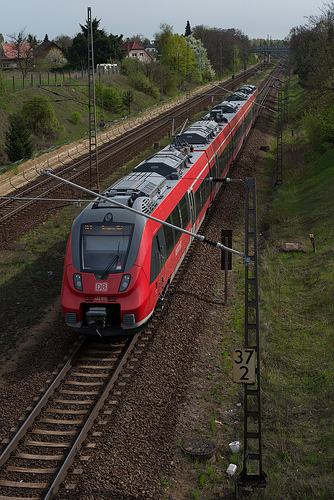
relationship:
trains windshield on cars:
[78, 220, 135, 274] [60, 83, 261, 342]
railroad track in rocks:
[1, 335, 147, 496] [5, 101, 267, 494]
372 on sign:
[234, 349, 255, 380] [228, 344, 258, 384]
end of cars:
[59, 208, 158, 333] [60, 83, 261, 342]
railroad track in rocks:
[1, 335, 147, 499] [2, 193, 245, 497]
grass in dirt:
[194, 305, 238, 492] [160, 291, 246, 493]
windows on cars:
[148, 102, 256, 269] [60, 83, 261, 342]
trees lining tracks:
[280, 4, 333, 149] [0, 330, 136, 493]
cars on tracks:
[60, 83, 261, 342] [2, 337, 145, 497]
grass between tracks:
[258, 79, 333, 498] [2, 337, 145, 497]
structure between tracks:
[87, 7, 99, 194] [2, 337, 145, 497]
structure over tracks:
[87, 7, 97, 197] [2, 337, 145, 497]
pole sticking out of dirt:
[223, 237, 230, 301] [186, 298, 233, 427]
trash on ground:
[227, 439, 241, 477] [171, 301, 241, 497]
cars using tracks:
[60, 83, 261, 342] [2, 337, 145, 497]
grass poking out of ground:
[258, 79, 334, 499] [176, 301, 220, 497]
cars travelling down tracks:
[60, 83, 261, 342] [2, 337, 145, 497]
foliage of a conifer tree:
[5, 109, 35, 160] [4, 111, 36, 162]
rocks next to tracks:
[5, 101, 267, 494] [9, 364, 92, 493]